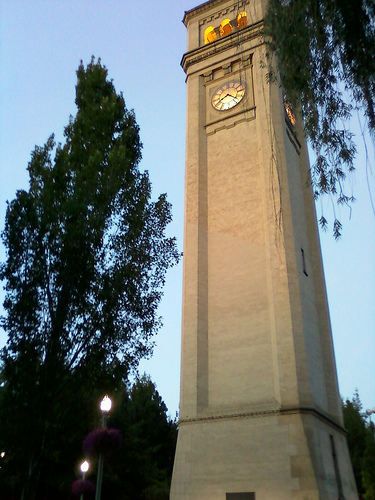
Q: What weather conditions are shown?
A: It is clear.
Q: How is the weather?
A: It is clear.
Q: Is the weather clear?
A: Yes, it is clear.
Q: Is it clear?
A: Yes, it is clear.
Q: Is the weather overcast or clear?
A: It is clear.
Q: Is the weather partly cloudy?
A: No, it is clear.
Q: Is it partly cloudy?
A: No, it is clear.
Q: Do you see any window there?
A: Yes, there is a window.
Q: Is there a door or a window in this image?
A: Yes, there is a window.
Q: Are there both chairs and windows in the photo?
A: No, there is a window but no chairs.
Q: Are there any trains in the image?
A: No, there are no trains.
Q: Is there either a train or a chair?
A: No, there are no trains or chairs.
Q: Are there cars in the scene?
A: No, there are no cars.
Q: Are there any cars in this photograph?
A: No, there are no cars.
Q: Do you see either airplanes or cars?
A: No, there are no cars or airplanes.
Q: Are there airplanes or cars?
A: No, there are no cars or airplanes.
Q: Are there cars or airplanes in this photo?
A: No, there are no cars or airplanes.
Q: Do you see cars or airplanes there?
A: No, there are no cars or airplanes.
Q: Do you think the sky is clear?
A: Yes, the sky is clear.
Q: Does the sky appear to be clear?
A: Yes, the sky is clear.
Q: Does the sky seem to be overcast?
A: No, the sky is clear.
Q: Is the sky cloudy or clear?
A: The sky is clear.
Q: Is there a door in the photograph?
A: Yes, there is a door.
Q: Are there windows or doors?
A: Yes, there is a door.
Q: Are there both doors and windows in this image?
A: Yes, there are both a door and a window.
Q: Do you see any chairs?
A: No, there are no chairs.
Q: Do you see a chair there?
A: No, there are no chairs.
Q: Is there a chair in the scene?
A: No, there are no chairs.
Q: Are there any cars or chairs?
A: No, there are no chairs or cars.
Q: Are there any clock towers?
A: Yes, there is a clock tower.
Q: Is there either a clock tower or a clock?
A: Yes, there is a clock tower.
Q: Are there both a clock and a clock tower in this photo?
A: Yes, there are both a clock tower and a clock.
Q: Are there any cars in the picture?
A: No, there are no cars.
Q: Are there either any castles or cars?
A: No, there are no cars or castles.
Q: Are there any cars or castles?
A: No, there are no cars or castles.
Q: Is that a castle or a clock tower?
A: That is a clock tower.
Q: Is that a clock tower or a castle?
A: That is a clock tower.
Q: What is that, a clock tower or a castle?
A: That is a clock tower.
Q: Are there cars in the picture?
A: No, there are no cars.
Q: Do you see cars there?
A: No, there are no cars.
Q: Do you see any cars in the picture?
A: No, there are no cars.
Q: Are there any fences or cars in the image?
A: No, there are no cars or fences.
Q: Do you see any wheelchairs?
A: No, there are no wheelchairs.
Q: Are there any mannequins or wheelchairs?
A: No, there are no wheelchairs or mannequins.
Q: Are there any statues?
A: No, there are no statues.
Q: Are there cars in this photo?
A: No, there are no cars.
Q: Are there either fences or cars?
A: No, there are no cars or fences.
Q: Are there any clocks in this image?
A: Yes, there is a clock.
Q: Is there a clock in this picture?
A: Yes, there is a clock.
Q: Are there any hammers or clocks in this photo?
A: Yes, there is a clock.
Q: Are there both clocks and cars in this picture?
A: No, there is a clock but no cars.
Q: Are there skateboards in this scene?
A: No, there are no skateboards.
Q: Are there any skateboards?
A: No, there are no skateboards.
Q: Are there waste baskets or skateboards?
A: No, there are no skateboards or waste baskets.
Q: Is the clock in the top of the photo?
A: Yes, the clock is in the top of the image.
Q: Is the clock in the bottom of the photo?
A: No, the clock is in the top of the image.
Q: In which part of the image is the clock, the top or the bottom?
A: The clock is in the top of the image.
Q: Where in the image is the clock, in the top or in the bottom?
A: The clock is in the top of the image.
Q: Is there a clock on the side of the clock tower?
A: Yes, there is a clock on the side of the clock tower.